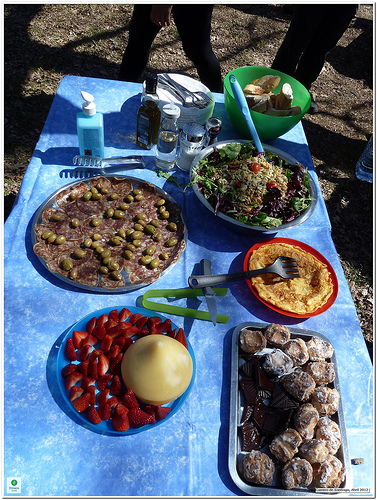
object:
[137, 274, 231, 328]
tongs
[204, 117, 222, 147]
shaker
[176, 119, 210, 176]
bottle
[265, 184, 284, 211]
olive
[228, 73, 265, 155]
knife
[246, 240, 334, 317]
platei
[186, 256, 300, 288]
fork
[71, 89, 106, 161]
soap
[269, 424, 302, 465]
tray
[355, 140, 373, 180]
shoe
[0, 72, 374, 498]
tablecloth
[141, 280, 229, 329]
green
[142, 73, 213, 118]
plates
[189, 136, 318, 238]
bowl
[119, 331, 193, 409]
sauce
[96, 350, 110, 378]
strawberries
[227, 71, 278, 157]
spoon